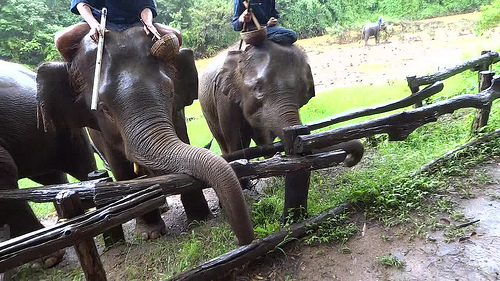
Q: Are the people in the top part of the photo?
A: Yes, the people are in the top of the image.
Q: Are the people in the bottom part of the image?
A: No, the people are in the top of the image.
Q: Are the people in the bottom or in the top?
A: The people are in the top of the image.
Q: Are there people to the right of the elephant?
A: Yes, there are people to the right of the elephant.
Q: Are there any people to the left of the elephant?
A: No, the people are to the right of the elephant.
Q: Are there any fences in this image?
A: Yes, there is a fence.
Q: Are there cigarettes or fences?
A: Yes, there is a fence.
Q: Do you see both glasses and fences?
A: No, there is a fence but no glasses.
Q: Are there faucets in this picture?
A: No, there are no faucets.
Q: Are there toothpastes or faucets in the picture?
A: No, there are no faucets or toothpastes.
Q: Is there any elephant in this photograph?
A: Yes, there is an elephant.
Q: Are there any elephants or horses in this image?
A: Yes, there is an elephant.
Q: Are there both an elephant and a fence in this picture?
A: Yes, there are both an elephant and a fence.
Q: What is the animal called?
A: The animal is an elephant.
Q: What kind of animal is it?
A: The animal is an elephant.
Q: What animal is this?
A: This is an elephant.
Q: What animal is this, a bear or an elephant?
A: This is an elephant.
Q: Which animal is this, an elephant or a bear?
A: This is an elephant.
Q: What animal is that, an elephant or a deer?
A: That is an elephant.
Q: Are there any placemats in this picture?
A: No, there are no placemats.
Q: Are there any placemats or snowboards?
A: No, there are no placemats or snowboards.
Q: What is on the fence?
A: The trunk is on the fence.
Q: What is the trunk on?
A: The trunk is on the fence.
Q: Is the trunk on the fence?
A: Yes, the trunk is on the fence.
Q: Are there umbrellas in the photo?
A: No, there are no umbrellas.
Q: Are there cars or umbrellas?
A: No, there are no umbrellas or cars.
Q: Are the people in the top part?
A: Yes, the people are in the top of the image.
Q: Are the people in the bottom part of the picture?
A: No, the people are in the top of the image.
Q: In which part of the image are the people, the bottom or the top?
A: The people are in the top of the image.